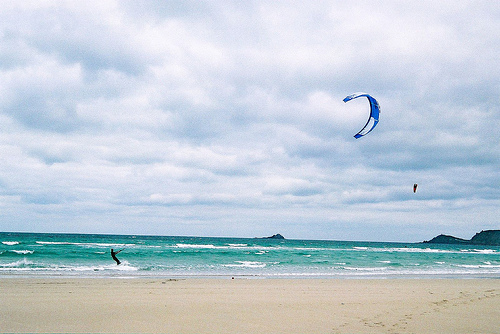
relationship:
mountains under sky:
[264, 229, 500, 246] [0, 1, 499, 244]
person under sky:
[110, 245, 127, 264] [0, 1, 499, 244]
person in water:
[110, 245, 127, 264] [0, 231, 500, 278]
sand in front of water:
[0, 276, 499, 334] [0, 231, 500, 278]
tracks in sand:
[336, 287, 498, 334] [0, 276, 499, 334]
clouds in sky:
[0, 1, 499, 232] [0, 1, 499, 244]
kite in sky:
[343, 91, 381, 138] [0, 1, 499, 244]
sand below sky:
[0, 276, 499, 334] [0, 1, 499, 244]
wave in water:
[0, 238, 499, 271] [0, 231, 500, 278]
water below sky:
[0, 231, 500, 278] [0, 1, 499, 244]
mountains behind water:
[264, 229, 500, 246] [0, 231, 500, 278]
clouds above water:
[0, 1, 499, 232] [0, 231, 500, 278]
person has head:
[110, 245, 127, 264] [110, 247, 114, 253]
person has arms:
[110, 245, 127, 264] [114, 248, 124, 256]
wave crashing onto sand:
[0, 238, 499, 271] [0, 276, 499, 334]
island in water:
[262, 233, 285, 239] [0, 231, 500, 278]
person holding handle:
[110, 245, 127, 264] [121, 246, 128, 252]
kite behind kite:
[412, 182, 419, 192] [343, 91, 381, 138]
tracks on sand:
[336, 287, 498, 334] [0, 276, 499, 334]